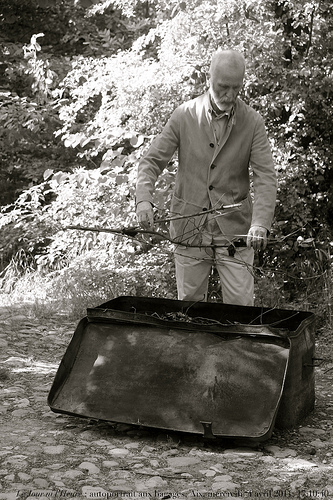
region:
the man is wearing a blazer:
[122, 93, 283, 317]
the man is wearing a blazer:
[150, 101, 253, 256]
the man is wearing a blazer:
[124, 20, 331, 274]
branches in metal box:
[117, 300, 263, 357]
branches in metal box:
[100, 271, 330, 388]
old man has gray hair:
[152, 43, 298, 199]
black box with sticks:
[43, 288, 323, 444]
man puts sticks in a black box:
[22, 37, 331, 456]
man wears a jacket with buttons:
[129, 41, 286, 259]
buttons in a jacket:
[203, 132, 224, 204]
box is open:
[37, 284, 330, 454]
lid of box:
[39, 310, 297, 454]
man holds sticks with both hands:
[63, 44, 313, 273]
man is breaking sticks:
[42, 44, 331, 287]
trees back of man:
[9, 5, 308, 290]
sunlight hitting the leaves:
[94, 78, 130, 132]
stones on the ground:
[22, 440, 100, 478]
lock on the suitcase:
[189, 411, 231, 435]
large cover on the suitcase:
[48, 315, 297, 445]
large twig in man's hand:
[63, 212, 297, 267]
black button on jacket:
[197, 140, 237, 159]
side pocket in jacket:
[230, 190, 252, 212]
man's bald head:
[189, 41, 257, 80]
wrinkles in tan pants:
[171, 252, 203, 287]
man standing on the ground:
[117, 50, 285, 305]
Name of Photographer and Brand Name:
[11, 478, 331, 498]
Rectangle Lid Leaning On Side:
[34, 308, 305, 454]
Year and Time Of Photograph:
[267, 485, 327, 499]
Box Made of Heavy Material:
[92, 283, 332, 429]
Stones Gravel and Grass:
[10, 428, 272, 499]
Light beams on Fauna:
[25, 18, 172, 259]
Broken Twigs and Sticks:
[42, 194, 285, 283]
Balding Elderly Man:
[159, 25, 258, 124]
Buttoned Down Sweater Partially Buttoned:
[170, 90, 305, 258]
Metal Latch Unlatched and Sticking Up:
[187, 396, 234, 447]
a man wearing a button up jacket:
[133, 40, 279, 310]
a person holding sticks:
[132, 50, 277, 310]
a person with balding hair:
[126, 45, 279, 308]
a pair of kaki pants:
[167, 218, 254, 310]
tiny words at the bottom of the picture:
[8, 487, 329, 497]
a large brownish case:
[45, 293, 317, 446]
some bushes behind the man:
[2, 3, 331, 316]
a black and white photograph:
[2, 5, 331, 496]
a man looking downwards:
[199, 43, 244, 121]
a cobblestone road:
[0, 304, 332, 498]